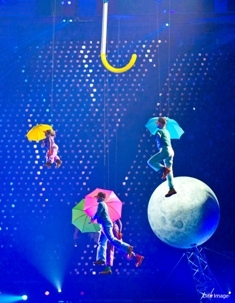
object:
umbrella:
[25, 124, 54, 142]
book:
[48, 149, 52, 154]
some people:
[44, 117, 178, 275]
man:
[147, 116, 176, 197]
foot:
[164, 188, 175, 198]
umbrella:
[83, 188, 122, 224]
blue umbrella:
[144, 116, 184, 140]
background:
[14, 15, 233, 125]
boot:
[132, 252, 144, 267]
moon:
[146, 175, 221, 249]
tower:
[157, 244, 234, 302]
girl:
[43, 129, 62, 167]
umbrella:
[71, 198, 100, 234]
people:
[98, 214, 144, 275]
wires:
[154, 1, 170, 116]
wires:
[50, 0, 56, 135]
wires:
[102, 66, 109, 192]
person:
[90, 193, 133, 266]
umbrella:
[143, 116, 184, 140]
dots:
[80, 45, 86, 49]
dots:
[79, 48, 84, 54]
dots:
[83, 53, 88, 58]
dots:
[81, 58, 86, 64]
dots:
[88, 68, 93, 73]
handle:
[100, 0, 136, 75]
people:
[44, 129, 62, 171]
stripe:
[0, 22, 167, 250]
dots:
[21, 71, 24, 76]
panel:
[3, 36, 220, 278]